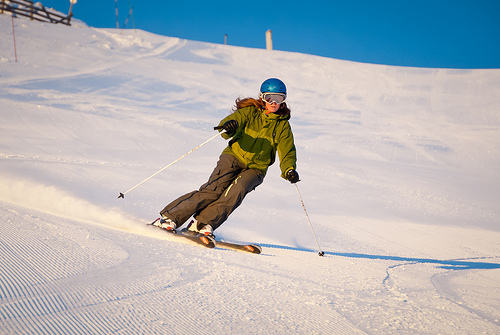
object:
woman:
[155, 78, 299, 247]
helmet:
[259, 77, 286, 96]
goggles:
[261, 92, 287, 103]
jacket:
[217, 105, 296, 179]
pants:
[159, 148, 267, 227]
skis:
[147, 224, 215, 248]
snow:
[2, 14, 500, 334]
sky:
[36, 0, 499, 69]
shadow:
[241, 242, 498, 270]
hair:
[233, 96, 265, 110]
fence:
[0, 0, 76, 26]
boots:
[181, 219, 216, 248]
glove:
[222, 119, 238, 133]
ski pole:
[118, 128, 227, 199]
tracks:
[4, 38, 189, 91]